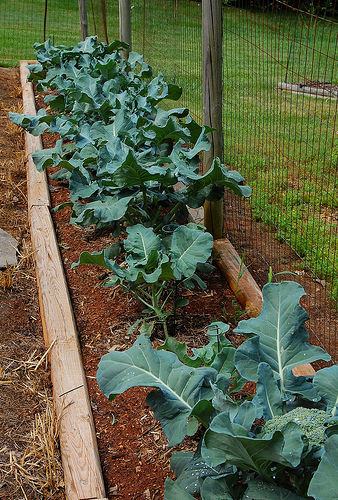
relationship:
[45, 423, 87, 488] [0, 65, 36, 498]
border nailed in ground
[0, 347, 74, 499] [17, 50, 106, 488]
dry grass by border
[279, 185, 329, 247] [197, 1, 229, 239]
wire connected to board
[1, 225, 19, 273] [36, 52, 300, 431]
rock by garden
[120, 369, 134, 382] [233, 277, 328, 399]
drops on leaf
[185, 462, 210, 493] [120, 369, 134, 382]
drops of drops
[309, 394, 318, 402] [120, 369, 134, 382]
drops of drops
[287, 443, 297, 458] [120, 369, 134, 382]
drops of drops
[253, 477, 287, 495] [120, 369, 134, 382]
drops of drops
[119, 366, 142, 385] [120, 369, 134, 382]
drops of drops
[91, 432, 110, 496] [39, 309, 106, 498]
edge of wood